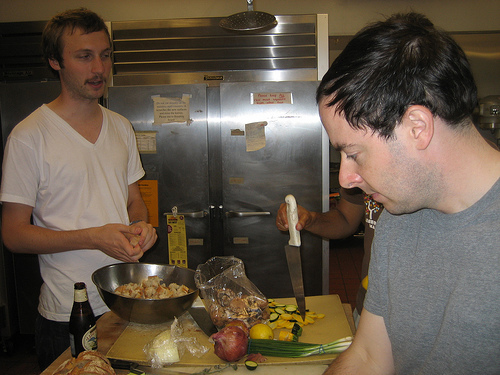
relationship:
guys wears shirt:
[1, 11, 157, 370] [2, 96, 152, 325]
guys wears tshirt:
[1, 11, 157, 370] [1, 102, 146, 321]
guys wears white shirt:
[1, 11, 157, 370] [3, 97, 150, 324]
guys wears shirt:
[313, 12, 500, 375] [355, 181, 498, 371]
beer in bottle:
[68, 282, 98, 356] [68, 282, 98, 354]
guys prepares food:
[313, 10, 498, 373] [210, 284, 353, 365]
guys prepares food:
[1, 5, 158, 354] [113, 273, 192, 300]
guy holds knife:
[277, 185, 384, 272] [282, 195, 306, 323]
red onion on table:
[208, 322, 250, 362] [62, 300, 357, 373]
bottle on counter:
[68, 282, 98, 354] [33, 292, 359, 374]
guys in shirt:
[1, 11, 157, 370] [2, 96, 152, 325]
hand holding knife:
[265, 180, 335, 248] [279, 191, 313, 319]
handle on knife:
[281, 190, 304, 248] [278, 186, 317, 326]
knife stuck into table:
[278, 186, 317, 326] [49, 291, 366, 371]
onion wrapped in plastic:
[145, 322, 187, 363] [134, 317, 212, 363]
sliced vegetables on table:
[252, 300, 337, 352] [102, 262, 343, 372]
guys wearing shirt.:
[1, 11, 157, 370] [11, 101, 140, 311]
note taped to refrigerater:
[243, 118, 268, 150] [4, 8, 345, 355]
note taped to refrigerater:
[153, 91, 190, 125] [4, 8, 345, 355]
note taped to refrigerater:
[164, 207, 186, 267] [4, 8, 345, 355]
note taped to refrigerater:
[140, 178, 160, 223] [4, 8, 345, 355]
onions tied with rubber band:
[249, 331, 354, 361] [317, 340, 325, 356]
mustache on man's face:
[81, 75, 108, 87] [61, 28, 111, 100]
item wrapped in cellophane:
[122, 264, 276, 374] [142, 310, 212, 362]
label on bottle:
[64, 320, 98, 362] [67, 273, 104, 356]